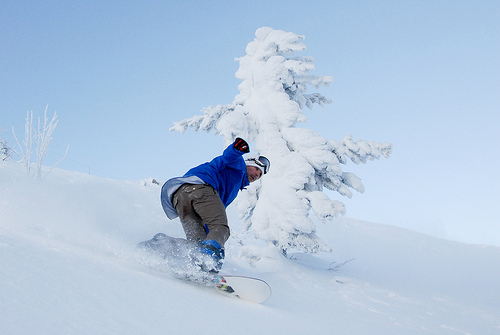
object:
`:
[244, 155, 269, 182]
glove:
[232, 137, 250, 155]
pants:
[170, 182, 231, 255]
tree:
[5, 96, 67, 183]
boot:
[195, 240, 224, 275]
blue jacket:
[159, 136, 249, 221]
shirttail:
[159, 175, 206, 220]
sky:
[54, 17, 157, 109]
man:
[159, 137, 271, 274]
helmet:
[244, 155, 271, 179]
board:
[136, 233, 275, 306]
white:
[342, 234, 408, 290]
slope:
[11, 161, 131, 319]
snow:
[269, 69, 326, 173]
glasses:
[244, 155, 271, 175]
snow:
[2, 155, 495, 332]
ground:
[1, 150, 496, 333]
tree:
[165, 23, 394, 264]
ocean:
[0, 158, 498, 334]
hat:
[244, 153, 267, 179]